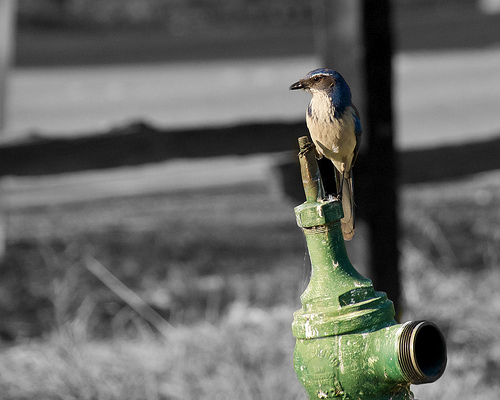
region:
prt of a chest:
[293, 88, 337, 133]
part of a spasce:
[410, 318, 445, 350]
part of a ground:
[199, 333, 242, 367]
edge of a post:
[278, 282, 349, 367]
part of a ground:
[186, 329, 229, 371]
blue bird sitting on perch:
[289, 64, 368, 247]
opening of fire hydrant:
[310, 320, 446, 385]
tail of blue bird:
[328, 177, 359, 233]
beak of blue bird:
[290, 81, 302, 100]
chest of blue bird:
[310, 97, 329, 159]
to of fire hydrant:
[276, 201, 338, 229]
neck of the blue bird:
[335, 89, 350, 107]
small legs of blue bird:
[332, 180, 341, 207]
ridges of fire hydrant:
[395, 349, 417, 365]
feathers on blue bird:
[315, 110, 339, 125]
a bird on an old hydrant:
[224, 70, 449, 385]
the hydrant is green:
[261, 148, 456, 388]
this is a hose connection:
[349, 291, 455, 396]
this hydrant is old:
[276, 193, 454, 389]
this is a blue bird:
[285, 74, 405, 215]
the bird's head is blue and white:
[289, 66, 356, 114]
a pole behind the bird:
[305, 2, 401, 304]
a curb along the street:
[5, 11, 285, 243]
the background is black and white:
[13, 34, 487, 386]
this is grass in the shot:
[20, 182, 298, 307]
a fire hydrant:
[281, 205, 424, 394]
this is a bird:
[263, 46, 381, 243]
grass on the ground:
[41, 296, 163, 376]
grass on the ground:
[151, 302, 259, 382]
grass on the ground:
[26, 253, 114, 317]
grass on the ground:
[372, 240, 483, 305]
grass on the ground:
[204, 337, 288, 389]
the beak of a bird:
[283, 69, 308, 97]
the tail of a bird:
[327, 166, 359, 250]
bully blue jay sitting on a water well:
[287, 67, 363, 241]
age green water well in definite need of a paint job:
[290, 136, 448, 398]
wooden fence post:
[319, 1, 399, 322]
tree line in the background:
[14, 0, 322, 35]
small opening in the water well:
[411, 322, 446, 381]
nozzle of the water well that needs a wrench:
[293, 135, 344, 229]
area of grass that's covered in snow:
[400, 172, 498, 399]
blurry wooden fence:
[0, 0, 499, 321]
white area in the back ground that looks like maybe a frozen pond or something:
[10, 58, 320, 141]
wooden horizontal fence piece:
[11, 28, 315, 64]